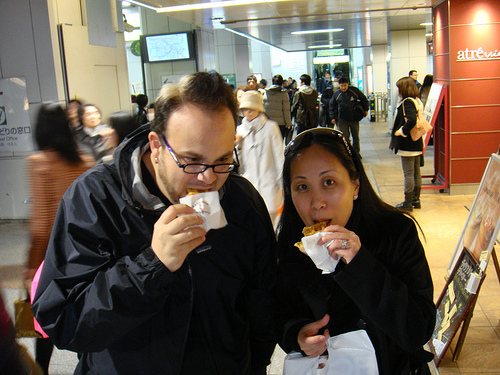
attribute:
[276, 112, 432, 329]
woman — waiting, eating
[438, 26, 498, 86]
sign — red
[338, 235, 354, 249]
ring — silver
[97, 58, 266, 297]
man — eating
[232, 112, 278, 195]
coat — white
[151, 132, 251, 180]
eyeglasses — black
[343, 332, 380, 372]
sack — plastic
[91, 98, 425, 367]
people — eating, standing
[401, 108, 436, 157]
purse — beige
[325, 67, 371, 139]
person — walking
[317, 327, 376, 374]
bag — white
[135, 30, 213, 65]
monitor — mounted, on left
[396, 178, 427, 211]
boots — black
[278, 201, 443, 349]
jacket — black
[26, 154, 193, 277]
jacket — black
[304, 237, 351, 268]
tissue — white